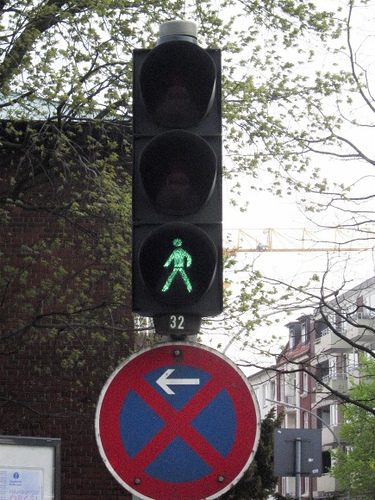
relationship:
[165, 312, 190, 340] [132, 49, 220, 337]
number on base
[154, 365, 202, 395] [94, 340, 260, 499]
arrow on sign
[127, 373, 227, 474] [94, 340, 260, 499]
x on sign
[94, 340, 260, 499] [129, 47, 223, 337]
sign near light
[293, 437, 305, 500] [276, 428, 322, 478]
pole and sign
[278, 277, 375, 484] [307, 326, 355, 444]
building has stories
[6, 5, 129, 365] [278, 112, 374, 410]
tress overhanging branches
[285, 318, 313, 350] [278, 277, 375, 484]
windows on building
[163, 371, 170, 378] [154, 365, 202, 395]
spot on arrow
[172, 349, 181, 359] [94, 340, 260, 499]
screw on sign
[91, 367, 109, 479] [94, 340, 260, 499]
edge of sign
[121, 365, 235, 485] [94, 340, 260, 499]
circle on sign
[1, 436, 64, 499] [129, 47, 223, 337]
sign by light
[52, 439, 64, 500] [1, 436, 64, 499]
edge on sign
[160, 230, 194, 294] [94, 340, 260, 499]
person on sign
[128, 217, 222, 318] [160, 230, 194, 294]
signal of person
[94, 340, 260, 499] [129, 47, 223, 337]
sign below light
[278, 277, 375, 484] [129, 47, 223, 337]
building behind light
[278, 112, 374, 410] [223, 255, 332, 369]
branches with leaves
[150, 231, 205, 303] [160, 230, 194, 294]
light shows person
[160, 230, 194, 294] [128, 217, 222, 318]
person on signal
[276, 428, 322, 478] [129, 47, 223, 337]
sign behind light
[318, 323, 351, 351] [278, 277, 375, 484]
balcony on building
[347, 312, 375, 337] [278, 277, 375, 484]
balcony on building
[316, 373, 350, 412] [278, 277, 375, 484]
balcony on building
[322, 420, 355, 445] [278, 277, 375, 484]
balcony on building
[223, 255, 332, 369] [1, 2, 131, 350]
leaves of tree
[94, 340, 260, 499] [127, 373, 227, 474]
sign with x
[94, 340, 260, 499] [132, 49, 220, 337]
sign on signal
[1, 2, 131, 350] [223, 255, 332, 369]
tree with leaves